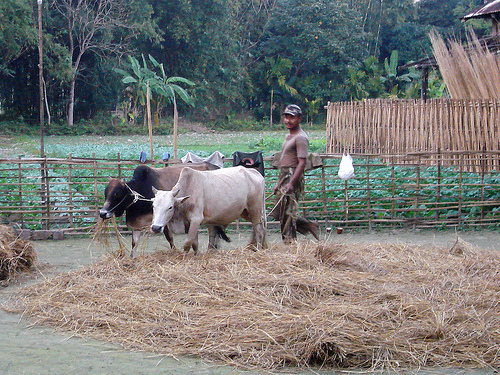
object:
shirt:
[275, 130, 307, 166]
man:
[274, 104, 318, 242]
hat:
[283, 103, 303, 116]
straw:
[295, 315, 337, 337]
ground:
[0, 232, 499, 374]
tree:
[54, 0, 131, 126]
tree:
[260, 55, 293, 127]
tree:
[174, 0, 229, 124]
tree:
[1, 1, 74, 124]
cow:
[149, 166, 268, 253]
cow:
[98, 162, 223, 257]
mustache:
[284, 121, 293, 127]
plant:
[365, 188, 391, 200]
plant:
[47, 182, 71, 190]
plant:
[77, 147, 105, 154]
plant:
[441, 170, 460, 178]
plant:
[417, 206, 439, 216]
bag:
[337, 151, 355, 181]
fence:
[0, 149, 497, 228]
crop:
[46, 184, 88, 215]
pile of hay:
[14, 239, 499, 372]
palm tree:
[147, 52, 197, 158]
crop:
[128, 152, 140, 158]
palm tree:
[116, 53, 160, 161]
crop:
[157, 145, 171, 153]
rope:
[122, 181, 143, 211]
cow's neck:
[123, 176, 144, 209]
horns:
[151, 185, 160, 194]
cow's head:
[147, 184, 191, 231]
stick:
[265, 190, 275, 199]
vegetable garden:
[0, 144, 497, 227]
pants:
[275, 166, 309, 243]